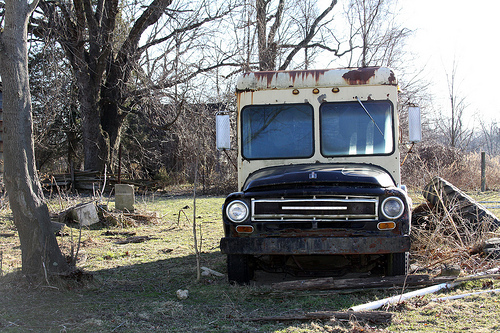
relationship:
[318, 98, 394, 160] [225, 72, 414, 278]
windshield on truck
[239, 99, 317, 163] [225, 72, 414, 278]
windshield of truck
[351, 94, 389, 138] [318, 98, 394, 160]
windshield wiper on windshield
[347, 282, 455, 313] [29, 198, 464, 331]
pole on ground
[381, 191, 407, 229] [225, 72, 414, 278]
headlight on truck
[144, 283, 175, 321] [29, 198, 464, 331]
grass on ground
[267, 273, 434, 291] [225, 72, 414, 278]
log front truck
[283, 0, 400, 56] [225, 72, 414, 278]
branches above truck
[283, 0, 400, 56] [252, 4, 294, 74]
branches of tree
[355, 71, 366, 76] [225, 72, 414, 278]
metal on truck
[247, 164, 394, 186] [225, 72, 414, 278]
hood of truck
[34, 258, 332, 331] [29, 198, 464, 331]
shadow on ground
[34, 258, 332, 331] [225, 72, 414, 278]
shadow of truck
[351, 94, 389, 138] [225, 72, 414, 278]
windshield wiper on truck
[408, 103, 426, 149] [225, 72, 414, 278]
mirror on truck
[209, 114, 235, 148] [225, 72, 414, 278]
mirror on truck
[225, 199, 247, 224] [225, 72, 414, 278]
headlight on truck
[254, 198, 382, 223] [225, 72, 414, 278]
grill of truck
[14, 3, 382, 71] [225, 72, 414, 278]
trees near vehicle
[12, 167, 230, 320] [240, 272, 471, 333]
yard has articles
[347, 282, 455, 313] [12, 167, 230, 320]
fence post in yard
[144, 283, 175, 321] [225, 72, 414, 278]
grass around truck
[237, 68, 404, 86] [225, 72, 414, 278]
top of truck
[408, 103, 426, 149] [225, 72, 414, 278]
mirror of truck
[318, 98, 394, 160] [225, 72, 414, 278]
window of truck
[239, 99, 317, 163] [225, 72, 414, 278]
window of truck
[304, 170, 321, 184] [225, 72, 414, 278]
emblem on truck